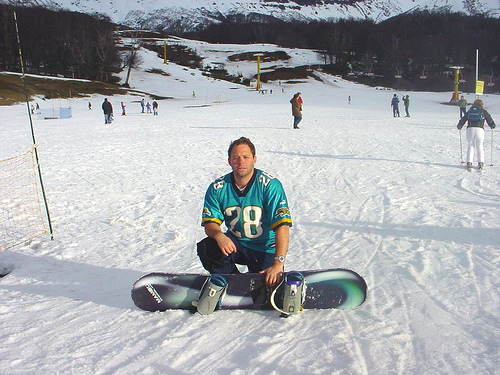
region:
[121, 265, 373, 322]
Snowboard is black with green design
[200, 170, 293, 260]
Man wearing football jersey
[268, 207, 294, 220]
Picture of a panther on sleeve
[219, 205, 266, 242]
Jersey number is 28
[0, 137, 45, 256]
Yellow net in corner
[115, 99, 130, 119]
Child on skis in snow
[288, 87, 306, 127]
Person holding a child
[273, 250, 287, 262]
Man is wearing a watch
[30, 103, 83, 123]
Mesh net blocking a hole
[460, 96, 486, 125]
Woman is wearing a blue backpack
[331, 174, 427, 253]
numerous tracks in the snow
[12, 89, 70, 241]
pink fence in the snow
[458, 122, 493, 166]
woman wearing white pants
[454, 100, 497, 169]
woman balancing on ski poles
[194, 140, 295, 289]
man kneeling in the snow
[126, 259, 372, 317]
neon colored ski board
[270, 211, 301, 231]
yellow collar on end of sleeve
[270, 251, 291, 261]
silver watch on man's hand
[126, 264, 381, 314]
Standard snowboard for boarding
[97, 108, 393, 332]
A snowboarding enthusiest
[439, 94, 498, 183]
Lady learning to ski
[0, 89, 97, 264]
Fencing to direct individuals on ski slope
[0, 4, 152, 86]
Edged green with forest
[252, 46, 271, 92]
Yellow ski lift supporting beem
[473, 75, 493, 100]
Sign for skier information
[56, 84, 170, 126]
group of individuals playing in the snow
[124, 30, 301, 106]
Ski resort lift for transporting people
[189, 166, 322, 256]
Turquoise jersey with number 28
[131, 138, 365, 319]
man kneeling by a snowboard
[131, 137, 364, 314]
man with a snowboard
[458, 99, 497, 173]
woman wearing a black coat and white pants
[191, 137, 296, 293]
man wearing a watch and a jersey with the number 28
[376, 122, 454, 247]
shadows being cast on the snow from the sun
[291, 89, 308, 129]
person in a brown coat carrying a child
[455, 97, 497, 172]
skier wearing a backpack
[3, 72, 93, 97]
brown grass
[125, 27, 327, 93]
hills partially covered with snow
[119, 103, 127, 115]
child standing in the snow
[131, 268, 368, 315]
snowboard on its side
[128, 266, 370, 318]
snowboard sidewise on snow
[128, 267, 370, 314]
black and white green snowboard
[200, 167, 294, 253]
blue football jersey on a man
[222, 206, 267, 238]
number print on a jersey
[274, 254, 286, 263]
silver watch on a man's wrist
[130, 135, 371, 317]
man and his snowboard on snow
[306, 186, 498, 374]
lots of tracks in snow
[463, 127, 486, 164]
white pants on a skier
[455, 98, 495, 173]
female on skis